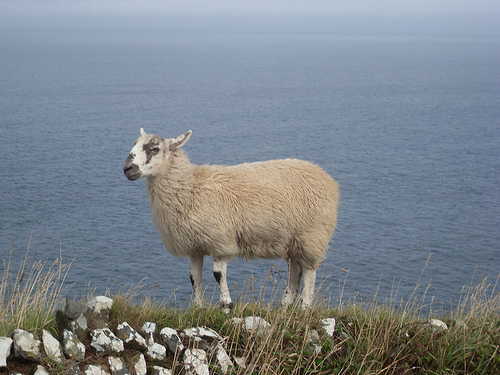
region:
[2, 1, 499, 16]
hazy blue sky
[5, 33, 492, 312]
choppy grey-blue water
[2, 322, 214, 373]
white and brown rocks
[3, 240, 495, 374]
grass and weeds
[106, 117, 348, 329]
a hairy white goat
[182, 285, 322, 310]
the goat's feet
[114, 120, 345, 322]
standing white goat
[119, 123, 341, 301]
goat with a black and white face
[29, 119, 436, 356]
a goat posing on a hill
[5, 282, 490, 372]
a hill by the water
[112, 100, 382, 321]
a goat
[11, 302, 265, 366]
some white rocks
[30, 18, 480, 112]
a beautiful blue ocean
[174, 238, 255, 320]
the sheeps front legs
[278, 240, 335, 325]
the sheeps hind legs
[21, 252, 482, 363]
some green and yellow grass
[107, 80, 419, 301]
a sheep standing above an ocean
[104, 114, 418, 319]
a sheep looking to the left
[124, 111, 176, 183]
a sheep with a brown and white face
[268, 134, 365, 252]
the sheeps but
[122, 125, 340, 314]
sheep standing beside a river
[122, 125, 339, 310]
tan and white sheep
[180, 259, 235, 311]
sheep's two white front legs with black spots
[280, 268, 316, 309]
two white back legs on the sheep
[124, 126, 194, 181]
black and white sheep's face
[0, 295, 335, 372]
dark grey and white rocks on the ground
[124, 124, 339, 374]
sheep standing on the ground behind rocks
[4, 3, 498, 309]
sheep standing before a river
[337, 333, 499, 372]
brown and white grass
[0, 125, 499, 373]
one sheep standing before a lake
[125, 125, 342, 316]
sheep standing on hillside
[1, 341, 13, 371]
first small rock next to other rocks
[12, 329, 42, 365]
second rock from the left on hill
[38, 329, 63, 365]
third small rock from the left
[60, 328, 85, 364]
fourth small rock from the left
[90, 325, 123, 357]
fifth small rock from the left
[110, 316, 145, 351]
sixth small rock from the left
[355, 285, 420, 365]
grass on top of hill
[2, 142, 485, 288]
water in background of sheep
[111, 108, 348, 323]
a lamb on a cliff overlooking the ocean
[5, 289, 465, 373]
the remains of a rock wall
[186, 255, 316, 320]
the legs of the lamb are white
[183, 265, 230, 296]
the two front legs are muddy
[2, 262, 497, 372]
grass is growing on the cliff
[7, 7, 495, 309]
the ocean is calm and blue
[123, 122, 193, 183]
the lamb's head is black and white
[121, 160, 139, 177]
the nose of the lamb is black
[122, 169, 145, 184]
the lamb's mouth is black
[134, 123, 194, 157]
the lamb's ears are facing back